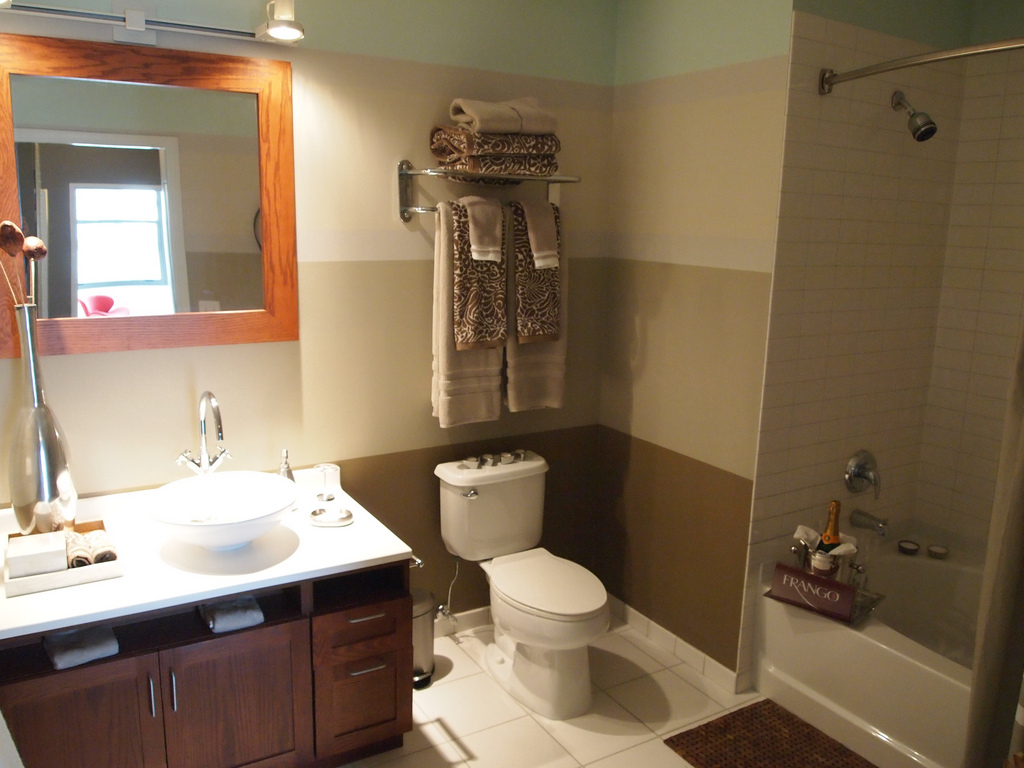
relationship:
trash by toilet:
[411, 600, 435, 694] [435, 446, 610, 715]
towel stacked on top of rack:
[437, 80, 558, 133] [391, 154, 590, 230]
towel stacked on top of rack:
[424, 119, 569, 156] [391, 154, 590, 230]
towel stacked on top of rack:
[434, 150, 562, 176] [391, 154, 590, 230]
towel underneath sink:
[43, 629, 123, 671] [138, 467, 309, 558]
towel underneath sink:
[195, 590, 267, 640] [138, 467, 309, 558]